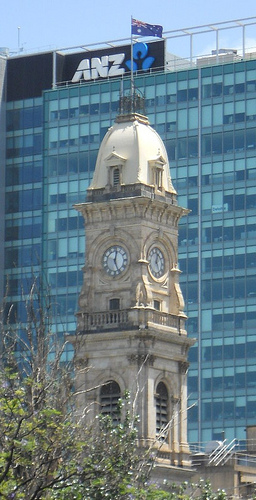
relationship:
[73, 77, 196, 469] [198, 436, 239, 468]
clock tower has stairs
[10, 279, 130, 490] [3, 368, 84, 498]
branches with leaves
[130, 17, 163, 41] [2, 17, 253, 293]
flag on building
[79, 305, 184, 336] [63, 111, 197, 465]
balcony on clock tower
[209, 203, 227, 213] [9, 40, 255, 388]
advertisement on building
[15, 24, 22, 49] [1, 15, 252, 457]
flag pole on building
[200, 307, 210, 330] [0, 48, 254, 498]
window on building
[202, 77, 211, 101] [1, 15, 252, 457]
window on building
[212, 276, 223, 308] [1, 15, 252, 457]
window on building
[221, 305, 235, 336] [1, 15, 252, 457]
window on building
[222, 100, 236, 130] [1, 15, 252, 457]
window on building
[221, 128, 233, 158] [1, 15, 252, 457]
window on building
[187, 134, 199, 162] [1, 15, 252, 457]
window on building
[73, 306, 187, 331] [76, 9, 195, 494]
railing on tower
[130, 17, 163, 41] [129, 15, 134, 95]
flag on pole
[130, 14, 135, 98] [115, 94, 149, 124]
pole on roof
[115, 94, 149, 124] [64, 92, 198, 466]
roof on building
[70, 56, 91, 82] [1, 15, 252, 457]
letter on building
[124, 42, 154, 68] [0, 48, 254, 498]
blue sign on building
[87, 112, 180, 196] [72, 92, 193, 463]
dome on tower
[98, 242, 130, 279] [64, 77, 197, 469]
clock on clock tower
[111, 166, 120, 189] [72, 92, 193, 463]
ventilation in tower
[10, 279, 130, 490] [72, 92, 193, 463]
branches by tower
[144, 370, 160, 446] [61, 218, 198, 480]
light on tower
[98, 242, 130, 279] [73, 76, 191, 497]
clock on building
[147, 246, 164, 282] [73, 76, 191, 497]
clock on building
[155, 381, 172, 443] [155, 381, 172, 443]
shutters on shutters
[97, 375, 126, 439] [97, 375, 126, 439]
blinds on blinds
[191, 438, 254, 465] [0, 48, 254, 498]
balcony on building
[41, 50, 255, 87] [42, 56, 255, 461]
roof on building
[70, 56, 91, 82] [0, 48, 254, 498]
letter on building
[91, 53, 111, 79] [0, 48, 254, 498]
letter on building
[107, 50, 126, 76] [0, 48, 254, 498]
letter on building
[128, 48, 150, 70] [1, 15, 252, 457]
blue man on building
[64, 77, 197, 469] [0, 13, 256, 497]
clock tower in front of building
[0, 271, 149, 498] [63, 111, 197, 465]
tree in front of clock tower